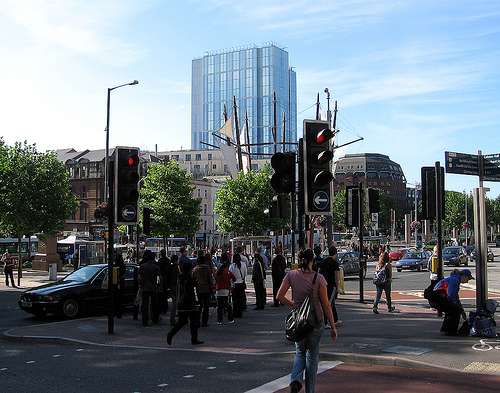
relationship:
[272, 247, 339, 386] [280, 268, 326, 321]
girl in shirt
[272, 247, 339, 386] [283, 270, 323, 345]
girl with bag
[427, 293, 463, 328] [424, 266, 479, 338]
pants on lady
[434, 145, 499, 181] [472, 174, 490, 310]
street sign on pole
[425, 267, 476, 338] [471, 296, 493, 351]
kneeling down with item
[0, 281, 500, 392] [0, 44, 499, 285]
pavement in city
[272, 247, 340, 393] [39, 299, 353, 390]
girl crossing street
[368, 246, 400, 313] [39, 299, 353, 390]
person crossing street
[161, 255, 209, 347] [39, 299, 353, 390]
person crossing street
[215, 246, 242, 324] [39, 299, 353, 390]
person crossing street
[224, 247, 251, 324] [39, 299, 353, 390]
person crossing street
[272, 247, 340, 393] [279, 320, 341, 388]
girl wearing jeans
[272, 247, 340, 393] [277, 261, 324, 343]
girl wearing bag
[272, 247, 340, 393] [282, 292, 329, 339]
girl wearing bag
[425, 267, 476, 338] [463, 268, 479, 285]
kneeling down wearing cap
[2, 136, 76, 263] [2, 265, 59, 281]
tree on sidewalk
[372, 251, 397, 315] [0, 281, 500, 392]
person walking on pavement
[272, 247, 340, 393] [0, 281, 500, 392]
girl walking on pavement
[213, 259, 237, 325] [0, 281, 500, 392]
person walking on pavement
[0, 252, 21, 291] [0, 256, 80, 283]
person standing on sidewalk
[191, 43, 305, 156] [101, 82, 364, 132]
building on background